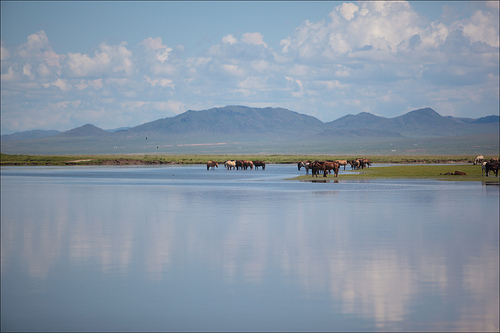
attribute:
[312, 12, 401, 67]
cloud — white, larger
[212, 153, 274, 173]
animals — wild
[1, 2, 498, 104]
clouds — white 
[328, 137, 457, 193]
grass — green 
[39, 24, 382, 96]
clouds — puffy, white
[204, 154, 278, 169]
animals — wild 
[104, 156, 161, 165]
shoreline — brown 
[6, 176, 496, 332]
water — large 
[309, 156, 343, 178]
horse — brown 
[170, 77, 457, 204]
mountain — big 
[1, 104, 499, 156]
mountains — hazy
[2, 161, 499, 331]
water — large, blue , calm 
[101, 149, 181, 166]
land — Green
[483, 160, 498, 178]
wild animal — brown, white, black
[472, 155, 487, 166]
wild animal — brown, white, black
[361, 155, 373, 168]
wild animal — brown, white, black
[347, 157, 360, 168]
wild animal — brown, white, black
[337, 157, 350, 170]
wild animal — brown, white, black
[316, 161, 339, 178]
wild animal — brown, white, black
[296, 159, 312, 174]
wild animal — brown, white, black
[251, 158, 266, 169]
wild animal — brown, white, black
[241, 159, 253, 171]
wild animal — brown, white, black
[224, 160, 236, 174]
wild animal — brown, white, black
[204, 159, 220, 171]
wild animal — brown, white, black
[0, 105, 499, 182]
land — small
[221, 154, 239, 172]
white horse — white 